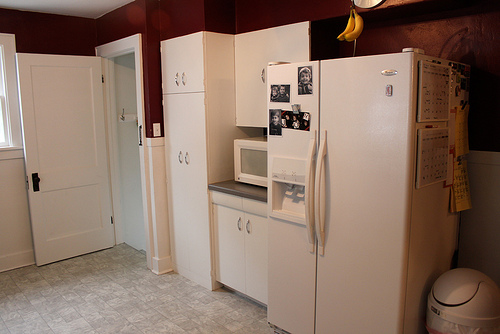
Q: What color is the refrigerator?
A: White.